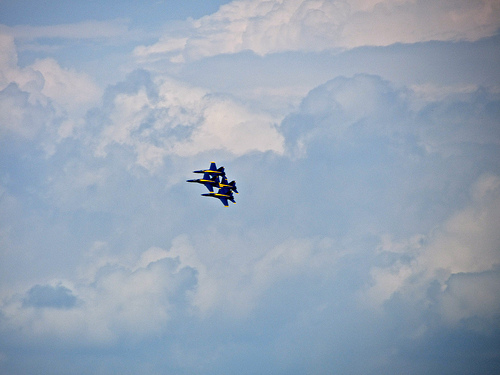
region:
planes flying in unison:
[172, 146, 241, 211]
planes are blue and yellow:
[182, 140, 242, 206]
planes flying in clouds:
[0, 0, 495, 325]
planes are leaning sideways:
[180, 105, 262, 230]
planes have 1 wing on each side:
[187, 140, 257, 222]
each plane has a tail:
[182, 150, 243, 215]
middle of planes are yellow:
[187, 155, 252, 230]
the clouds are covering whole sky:
[0, 1, 492, 326]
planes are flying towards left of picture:
[190, 152, 250, 212]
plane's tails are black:
[189, 149, 253, 232]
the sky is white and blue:
[99, 187, 317, 364]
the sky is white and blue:
[39, 204, 242, 364]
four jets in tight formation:
[183, 157, 245, 217]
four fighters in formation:
[185, 156, 240, 214]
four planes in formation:
[182, 151, 248, 218]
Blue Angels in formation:
[182, 157, 248, 218]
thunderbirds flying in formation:
[181, 146, 251, 230]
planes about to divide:
[177, 141, 258, 233]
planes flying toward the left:
[177, 138, 249, 221]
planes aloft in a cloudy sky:
[157, 136, 257, 253]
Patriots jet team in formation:
[189, 151, 249, 215]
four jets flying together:
[174, 149, 258, 218]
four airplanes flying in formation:
[185, 159, 238, 208]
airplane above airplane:
[193, 161, 225, 181]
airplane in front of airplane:
[191, 171, 221, 191]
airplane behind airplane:
[219, 174, 238, 194]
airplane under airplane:
[201, 186, 236, 207]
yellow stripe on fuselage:
[198, 178, 214, 183]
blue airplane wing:
[207, 160, 217, 172]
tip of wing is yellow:
[209, 160, 216, 165]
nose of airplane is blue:
[200, 190, 210, 195]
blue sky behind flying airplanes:
[0, 0, 498, 371]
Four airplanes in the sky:
[183, 154, 247, 213]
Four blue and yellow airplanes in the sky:
[182, 158, 239, 222]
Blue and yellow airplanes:
[181, 150, 246, 222]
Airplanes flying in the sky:
[182, 146, 262, 222]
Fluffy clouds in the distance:
[110, 14, 485, 331]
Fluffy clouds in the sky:
[129, 6, 496, 145]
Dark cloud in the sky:
[16, 278, 91, 320]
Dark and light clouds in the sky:
[93, 72, 278, 159]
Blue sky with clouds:
[9, 3, 230, 58]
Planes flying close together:
[170, 150, 260, 217]